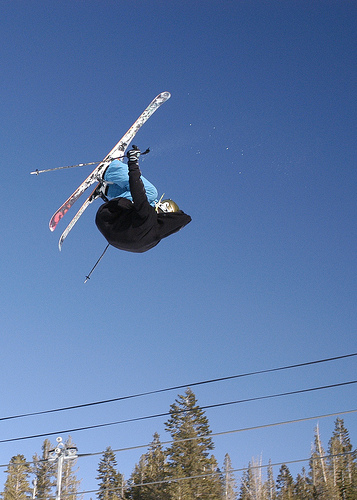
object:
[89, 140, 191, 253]
person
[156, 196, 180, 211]
helmet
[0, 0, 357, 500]
sky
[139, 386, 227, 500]
tree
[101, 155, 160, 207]
pants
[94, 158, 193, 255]
jacket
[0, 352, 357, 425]
wire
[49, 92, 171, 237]
ski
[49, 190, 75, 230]
graphic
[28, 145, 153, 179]
ski pole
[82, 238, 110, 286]
ski pole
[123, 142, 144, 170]
glove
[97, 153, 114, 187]
foot